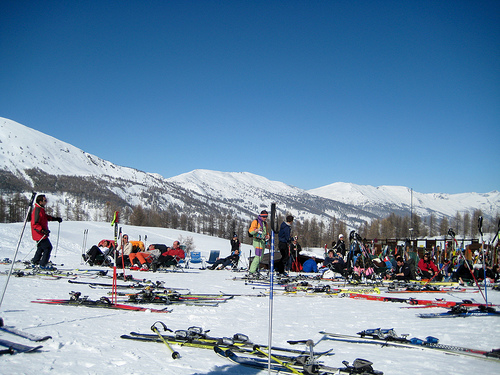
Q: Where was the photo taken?
A: Ski mountain.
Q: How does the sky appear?
A: Clear.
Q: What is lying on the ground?
A: Skis and poles.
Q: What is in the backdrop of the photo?
A: Mountains.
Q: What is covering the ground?
A: Snow.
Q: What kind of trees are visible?
A: Pine trees.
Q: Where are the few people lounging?
A: In chairs.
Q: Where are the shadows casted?
A: On ground.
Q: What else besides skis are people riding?
A: Snowboards.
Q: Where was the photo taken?
A: Ski resort.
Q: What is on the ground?
A: Snow.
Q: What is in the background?
A: Mountains.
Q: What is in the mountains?
A: Snow.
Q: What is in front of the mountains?
A: Line of trees.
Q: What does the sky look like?
A: Blue.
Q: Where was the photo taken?
A: Ski resort.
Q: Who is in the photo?
A: Skiers.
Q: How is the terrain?
A: Mountainous.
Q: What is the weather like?
A: Sunny.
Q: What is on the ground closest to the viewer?
A: Skis.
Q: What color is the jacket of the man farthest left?
A: Red.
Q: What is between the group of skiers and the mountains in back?
A: Trees.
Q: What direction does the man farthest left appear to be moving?
A: Left to right.